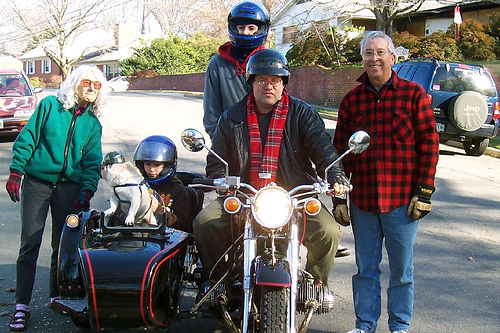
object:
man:
[330, 29, 438, 333]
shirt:
[335, 68, 441, 214]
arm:
[204, 114, 230, 175]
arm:
[302, 106, 339, 176]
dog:
[99, 151, 174, 227]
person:
[299, 25, 495, 331]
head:
[359, 32, 397, 78]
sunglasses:
[81, 78, 102, 90]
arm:
[415, 98, 443, 186]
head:
[246, 49, 290, 108]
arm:
[84, 132, 100, 183]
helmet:
[217, 0, 273, 51]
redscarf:
[244, 93, 290, 193]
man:
[193, 49, 356, 311]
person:
[206, 3, 276, 146]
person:
[2, 65, 104, 333]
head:
[226, 11, 268, 52]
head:
[133, 130, 177, 185]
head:
[65, 66, 106, 107]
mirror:
[179, 127, 206, 153]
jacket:
[205, 91, 346, 200]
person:
[110, 134, 198, 234]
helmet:
[244, 48, 291, 86]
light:
[304, 199, 323, 216]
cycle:
[45, 129, 368, 333]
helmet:
[134, 135, 178, 190]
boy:
[132, 134, 191, 232]